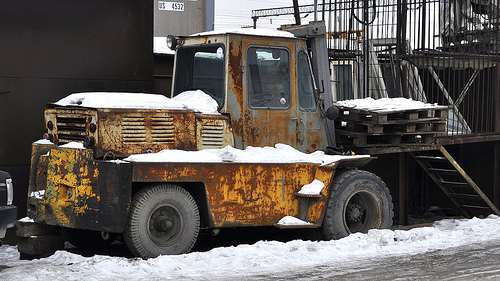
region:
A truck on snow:
[82, 87, 342, 242]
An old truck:
[69, 34, 376, 221]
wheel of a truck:
[113, 167, 203, 262]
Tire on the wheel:
[128, 189, 198, 244]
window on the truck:
[245, 49, 291, 111]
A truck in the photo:
[60, 97, 380, 266]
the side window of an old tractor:
[245, 48, 287, 108]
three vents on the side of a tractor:
[124, 112, 226, 149]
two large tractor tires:
[118, 169, 395, 259]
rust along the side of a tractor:
[130, 165, 339, 227]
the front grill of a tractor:
[44, 111, 98, 144]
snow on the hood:
[59, 91, 221, 111]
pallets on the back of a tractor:
[335, 93, 451, 144]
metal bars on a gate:
[313, 0, 498, 133]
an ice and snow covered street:
[4, 213, 496, 279]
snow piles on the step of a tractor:
[125, 143, 358, 160]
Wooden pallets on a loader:
[336, 98, 451, 138]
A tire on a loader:
[120, 185, 201, 255]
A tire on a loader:
[327, 168, 392, 234]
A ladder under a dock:
[420, 143, 490, 213]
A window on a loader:
[242, 40, 294, 112]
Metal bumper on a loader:
[26, 142, 126, 232]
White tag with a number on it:
[158, 0, 187, 10]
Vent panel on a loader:
[198, 118, 221, 145]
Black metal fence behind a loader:
[319, 4, 494, 124]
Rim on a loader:
[150, 215, 176, 235]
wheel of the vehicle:
[111, 152, 249, 257]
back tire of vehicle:
[315, 147, 407, 237]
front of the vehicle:
[38, 53, 159, 179]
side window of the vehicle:
[222, 21, 317, 126]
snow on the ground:
[278, 220, 392, 262]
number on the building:
[158, 1, 198, 20]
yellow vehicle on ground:
[21, 24, 322, 231]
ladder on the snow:
[409, 129, 494, 212]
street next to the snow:
[399, 233, 476, 279]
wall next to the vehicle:
[27, 11, 120, 65]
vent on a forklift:
[201, 125, 226, 129]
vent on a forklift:
[200, 130, 224, 134]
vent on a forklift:
[202, 142, 222, 146]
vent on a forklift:
[199, 138, 224, 143]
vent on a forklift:
[201, 132, 223, 137]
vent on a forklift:
[151, 114, 173, 119]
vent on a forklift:
[121, 113, 146, 118]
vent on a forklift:
[121, 125, 145, 130]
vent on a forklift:
[148, 124, 175, 131]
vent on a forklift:
[121, 133, 146, 140]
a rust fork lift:
[26, 30, 392, 255]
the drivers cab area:
[170, 30, 326, 160]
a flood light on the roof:
[162, 32, 177, 47]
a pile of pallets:
[331, 96, 447, 148]